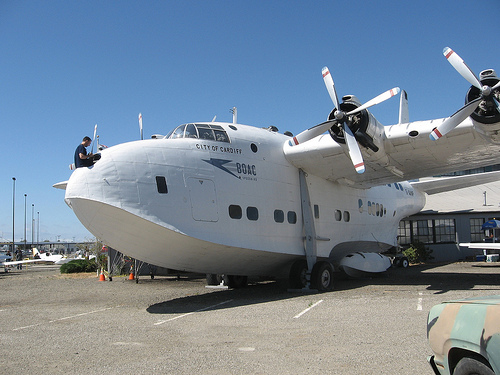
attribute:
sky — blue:
[0, 1, 499, 46]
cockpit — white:
[163, 122, 234, 143]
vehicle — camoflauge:
[416, 257, 498, 368]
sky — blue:
[0, 2, 499, 69]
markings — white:
[16, 300, 122, 332]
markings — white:
[154, 295, 230, 331]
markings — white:
[289, 296, 326, 321]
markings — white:
[411, 287, 428, 316]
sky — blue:
[28, 12, 495, 122]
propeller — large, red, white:
[284, 55, 414, 178]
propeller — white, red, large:
[271, 61, 408, 181]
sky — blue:
[5, 5, 498, 262]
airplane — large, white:
[30, 44, 496, 289]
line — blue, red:
[285, 132, 298, 149]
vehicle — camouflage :
[401, 294, 484, 374]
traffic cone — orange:
[95, 263, 110, 279]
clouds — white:
[23, 167, 58, 216]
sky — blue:
[79, 27, 239, 113]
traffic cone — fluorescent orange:
[99, 265, 106, 280]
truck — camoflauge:
[429, 292, 496, 374]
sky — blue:
[1, 0, 496, 242]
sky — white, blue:
[32, 19, 382, 79]